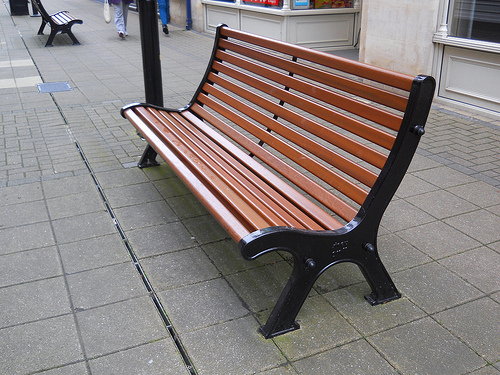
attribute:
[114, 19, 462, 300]
bench — shiny, black, brown, long, steel, metal, color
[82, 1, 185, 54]
person — walking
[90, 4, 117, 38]
bag — white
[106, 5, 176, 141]
pole — black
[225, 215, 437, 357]
leg — black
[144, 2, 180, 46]
jean — blue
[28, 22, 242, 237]
sidewalk — square